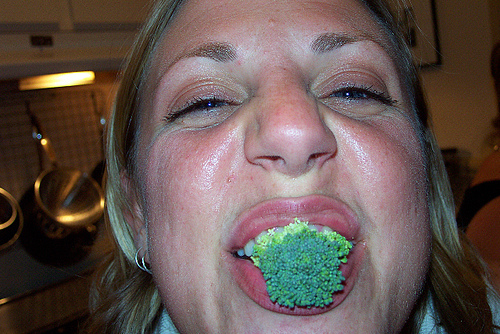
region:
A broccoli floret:
[243, 222, 357, 308]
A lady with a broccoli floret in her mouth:
[103, 0, 485, 332]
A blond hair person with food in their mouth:
[100, 1, 478, 332]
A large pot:
[29, 157, 105, 255]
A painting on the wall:
[388, 0, 446, 62]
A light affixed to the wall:
[13, 70, 103, 90]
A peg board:
[0, 58, 123, 300]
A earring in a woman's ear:
[133, 252, 153, 276]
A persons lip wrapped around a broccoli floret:
[231, 200, 370, 314]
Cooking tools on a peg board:
[0, 115, 124, 261]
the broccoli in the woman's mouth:
[250, 217, 353, 310]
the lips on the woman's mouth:
[226, 196, 366, 316]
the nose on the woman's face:
[243, 55, 338, 174]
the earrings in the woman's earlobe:
[134, 246, 154, 275]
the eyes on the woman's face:
[163, 63, 397, 118]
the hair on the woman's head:
[90, 0, 498, 333]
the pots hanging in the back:
[4, 96, 111, 248]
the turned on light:
[17, 70, 95, 91]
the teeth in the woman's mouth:
[234, 224, 334, 256]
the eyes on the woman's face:
[156, 30, 397, 84]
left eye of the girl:
[317, 58, 401, 127]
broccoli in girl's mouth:
[212, 190, 387, 320]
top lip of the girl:
[235, 185, 340, 228]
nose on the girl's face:
[231, 82, 352, 177]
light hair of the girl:
[427, 155, 482, 280]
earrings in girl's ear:
[112, 227, 172, 292]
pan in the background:
[22, 120, 109, 245]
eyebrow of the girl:
[144, 22, 254, 84]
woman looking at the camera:
[66, 10, 489, 318]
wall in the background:
[448, 25, 482, 81]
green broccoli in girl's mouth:
[244, 213, 368, 320]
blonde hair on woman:
[89, 143, 167, 285]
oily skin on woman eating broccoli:
[186, 148, 251, 195]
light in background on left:
[23, 65, 132, 100]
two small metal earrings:
[133, 248, 165, 280]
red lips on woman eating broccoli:
[213, 213, 363, 320]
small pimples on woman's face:
[257, 18, 289, 39]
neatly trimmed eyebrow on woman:
[308, 25, 375, 56]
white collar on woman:
[408, 300, 445, 332]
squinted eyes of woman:
[146, 88, 259, 128]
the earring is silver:
[125, 241, 161, 283]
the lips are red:
[246, 192, 358, 241]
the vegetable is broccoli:
[245, 220, 390, 325]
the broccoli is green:
[250, 221, 356, 327]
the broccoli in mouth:
[240, 196, 374, 312]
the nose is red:
[255, 83, 333, 178]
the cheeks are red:
[341, 129, 413, 243]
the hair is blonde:
[107, 175, 154, 325]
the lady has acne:
[173, 120, 416, 331]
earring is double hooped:
[123, 227, 160, 290]